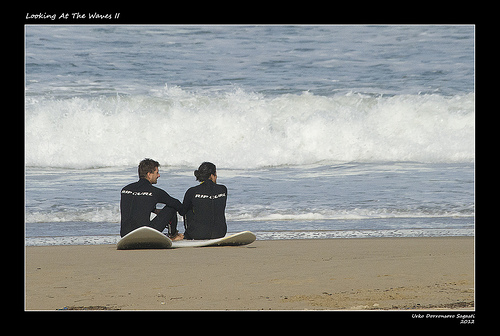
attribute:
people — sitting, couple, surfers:
[120, 155, 223, 234]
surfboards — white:
[121, 237, 253, 253]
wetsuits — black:
[119, 188, 225, 233]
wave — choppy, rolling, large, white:
[39, 90, 472, 170]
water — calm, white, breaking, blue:
[26, 31, 457, 91]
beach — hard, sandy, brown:
[48, 254, 465, 307]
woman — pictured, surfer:
[183, 152, 237, 248]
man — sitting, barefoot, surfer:
[115, 165, 180, 241]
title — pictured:
[22, 13, 119, 21]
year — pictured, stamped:
[450, 316, 472, 330]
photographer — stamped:
[404, 307, 470, 315]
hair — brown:
[140, 158, 156, 182]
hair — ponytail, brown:
[194, 168, 214, 180]